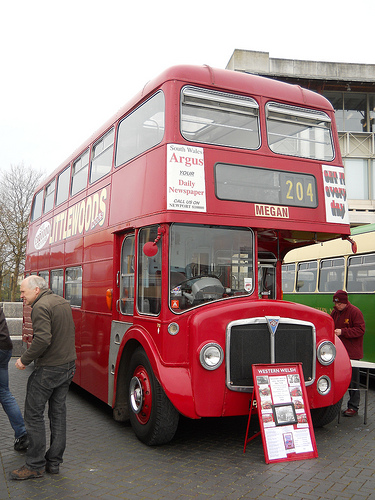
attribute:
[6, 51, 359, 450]
bus — red, double-decker, parked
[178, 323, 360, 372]
headlight — bus'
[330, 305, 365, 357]
coat — red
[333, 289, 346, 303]
cap — red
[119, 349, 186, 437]
wheel — front wheel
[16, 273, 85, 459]
man — wool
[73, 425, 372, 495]
parking space — grey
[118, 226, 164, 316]
windshield — side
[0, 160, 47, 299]
tree — without leaves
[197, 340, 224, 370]
headlight — silver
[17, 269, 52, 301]
hair — gray, white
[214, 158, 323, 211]
display — digital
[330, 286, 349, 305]
hat — red